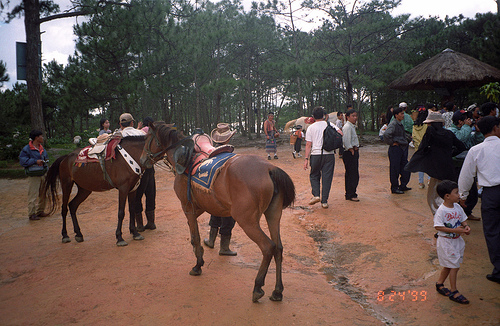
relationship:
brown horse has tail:
[139, 120, 297, 303] [269, 166, 299, 213]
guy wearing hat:
[204, 120, 239, 253] [210, 118, 235, 145]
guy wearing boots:
[204, 123, 238, 257] [202, 228, 239, 257]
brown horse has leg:
[41, 129, 146, 247] [57, 182, 72, 241]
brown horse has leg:
[41, 129, 146, 247] [67, 182, 89, 242]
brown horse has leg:
[41, 129, 146, 247] [114, 180, 128, 245]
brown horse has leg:
[41, 129, 146, 247] [129, 182, 141, 240]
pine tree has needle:
[42, 2, 186, 135] [125, 32, 132, 38]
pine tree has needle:
[42, 2, 186, 135] [173, 29, 179, 36]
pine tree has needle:
[42, 2, 186, 135] [132, 62, 139, 68]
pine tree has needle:
[42, 2, 186, 135] [109, 16, 119, 23]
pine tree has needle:
[42, 2, 186, 135] [140, 28, 147, 35]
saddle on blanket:
[188, 130, 241, 157] [175, 155, 241, 192]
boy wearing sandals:
[433, 180, 471, 305] [433, 282, 470, 305]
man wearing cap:
[395, 101, 414, 191] [394, 100, 408, 109]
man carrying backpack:
[303, 106, 343, 208] [321, 120, 344, 155]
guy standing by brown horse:
[204, 123, 238, 257] [139, 120, 297, 303]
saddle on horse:
[185, 127, 235, 175] [143, 127, 307, 304]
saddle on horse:
[83, 131, 116, 163] [15, 134, 155, 251]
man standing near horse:
[19, 130, 50, 220] [41, 124, 148, 246]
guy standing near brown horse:
[204, 123, 238, 257] [139, 120, 297, 303]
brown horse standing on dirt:
[139, 120, 297, 303] [1, 138, 492, 324]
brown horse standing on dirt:
[41, 129, 146, 247] [1, 138, 492, 324]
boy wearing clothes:
[431, 180, 471, 302] [433, 200, 466, 267]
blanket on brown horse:
[182, 152, 241, 193] [139, 120, 297, 303]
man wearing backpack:
[303, 101, 336, 131] [322, 118, 342, 152]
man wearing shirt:
[303, 101, 336, 131] [305, 119, 341, 155]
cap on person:
[399, 102, 408, 108] [406, 101, 469, 172]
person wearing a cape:
[406, 101, 469, 172] [398, 125, 474, 187]